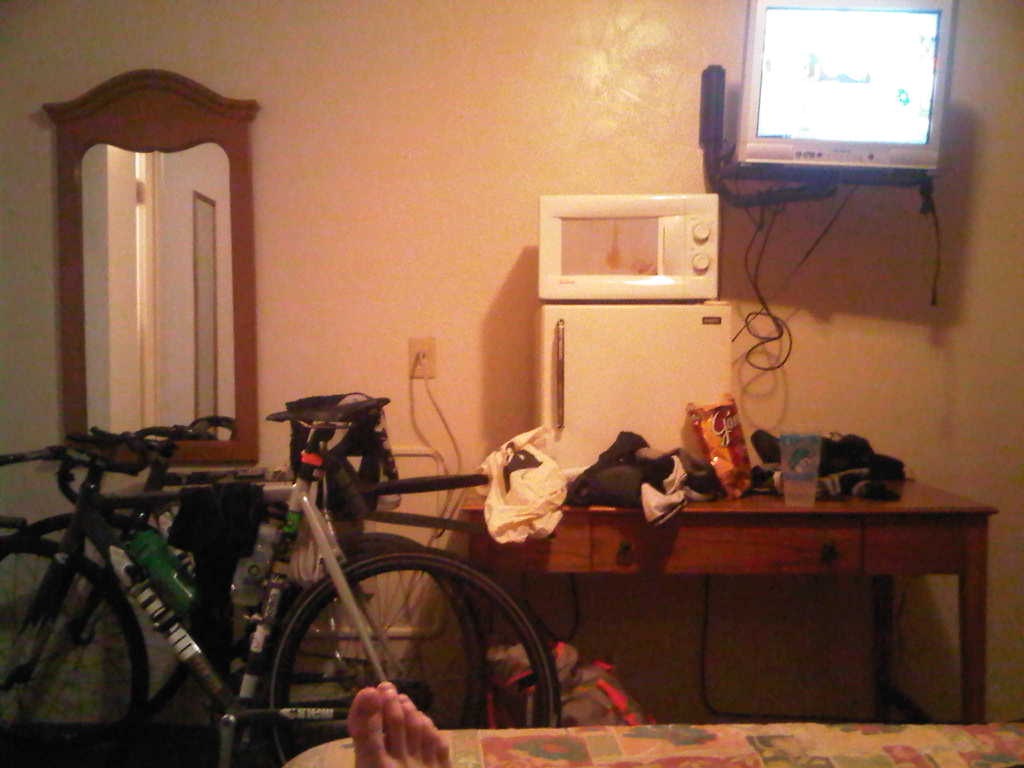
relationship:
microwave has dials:
[535, 188, 723, 306] [689, 219, 715, 278]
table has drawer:
[456, 469, 1001, 726] [581, 513, 862, 581]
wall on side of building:
[2, 1, 970, 714] [2, 1, 972, 764]